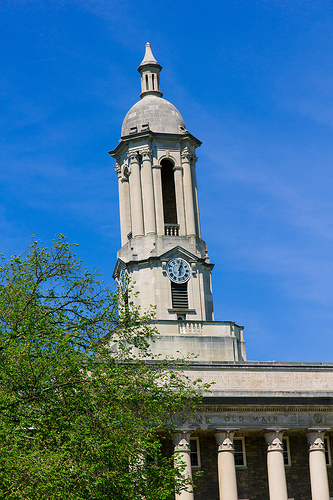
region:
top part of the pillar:
[130, 39, 172, 94]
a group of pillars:
[108, 428, 318, 499]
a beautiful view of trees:
[4, 237, 213, 481]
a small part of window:
[186, 433, 205, 470]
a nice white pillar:
[215, 437, 239, 497]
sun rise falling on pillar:
[213, 432, 245, 499]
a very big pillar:
[84, 45, 275, 493]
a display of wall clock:
[163, 247, 201, 294]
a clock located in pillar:
[160, 243, 199, 296]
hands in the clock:
[171, 262, 185, 273]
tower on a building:
[84, 35, 253, 364]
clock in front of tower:
[159, 253, 198, 288]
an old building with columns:
[77, 351, 330, 499]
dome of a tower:
[110, 35, 194, 133]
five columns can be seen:
[129, 428, 330, 499]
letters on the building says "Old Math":
[214, 409, 284, 430]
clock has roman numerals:
[158, 255, 197, 289]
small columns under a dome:
[111, 147, 207, 237]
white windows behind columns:
[152, 437, 331, 468]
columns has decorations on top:
[107, 143, 209, 184]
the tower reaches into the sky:
[83, 21, 331, 387]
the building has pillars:
[108, 397, 326, 496]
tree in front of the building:
[4, 243, 251, 484]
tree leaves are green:
[8, 241, 257, 495]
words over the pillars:
[189, 406, 276, 427]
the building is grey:
[103, 25, 324, 492]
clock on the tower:
[161, 246, 202, 302]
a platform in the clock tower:
[123, 126, 194, 257]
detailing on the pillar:
[213, 423, 233, 450]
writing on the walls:
[131, 362, 331, 411]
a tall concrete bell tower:
[93, 41, 247, 361]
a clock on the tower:
[163, 256, 193, 285]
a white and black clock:
[163, 255, 191, 284]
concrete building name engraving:
[222, 412, 283, 423]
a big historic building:
[26, 38, 331, 499]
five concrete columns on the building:
[117, 427, 332, 498]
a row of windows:
[145, 437, 330, 466]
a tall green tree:
[1, 233, 218, 498]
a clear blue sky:
[2, 0, 330, 363]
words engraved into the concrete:
[108, 367, 332, 389]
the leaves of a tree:
[43, 383, 85, 441]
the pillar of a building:
[210, 429, 242, 498]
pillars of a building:
[214, 429, 331, 494]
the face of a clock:
[165, 258, 194, 283]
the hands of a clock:
[175, 258, 185, 277]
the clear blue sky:
[257, 263, 294, 300]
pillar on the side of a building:
[128, 152, 160, 236]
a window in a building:
[232, 436, 248, 469]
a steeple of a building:
[133, 31, 170, 99]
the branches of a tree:
[47, 288, 79, 308]